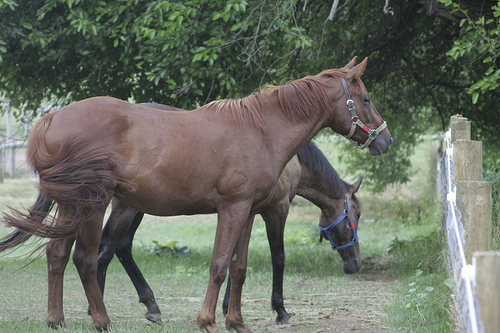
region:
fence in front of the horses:
[438, 101, 499, 331]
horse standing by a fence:
[21, 46, 391, 331]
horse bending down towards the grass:
[82, 135, 371, 322]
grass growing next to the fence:
[395, 198, 451, 325]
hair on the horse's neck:
[207, 63, 342, 141]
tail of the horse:
[22, 117, 122, 239]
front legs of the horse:
[193, 188, 262, 330]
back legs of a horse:
[43, 173, 111, 327]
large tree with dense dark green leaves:
[6, 0, 497, 172]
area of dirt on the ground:
[14, 270, 416, 331]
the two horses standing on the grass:
[1, 55, 392, 332]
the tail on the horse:
[0, 110, 138, 274]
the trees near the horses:
[0, 0, 496, 199]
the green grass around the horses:
[0, 131, 454, 331]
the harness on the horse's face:
[337, 70, 388, 150]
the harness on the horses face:
[317, 192, 357, 252]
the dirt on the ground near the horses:
[264, 258, 394, 331]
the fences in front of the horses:
[429, 111, 498, 331]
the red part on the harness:
[360, 123, 370, 132]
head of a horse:
[310, 39, 397, 159]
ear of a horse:
[332, 49, 379, 81]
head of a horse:
[316, 188, 379, 279]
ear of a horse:
[345, 173, 372, 196]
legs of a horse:
[29, 190, 296, 324]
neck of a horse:
[243, 67, 330, 175]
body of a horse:
[33, 96, 244, 224]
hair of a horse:
[237, 84, 322, 139]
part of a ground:
[325, 298, 334, 315]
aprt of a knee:
[199, 219, 246, 290]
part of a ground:
[356, 271, 366, 293]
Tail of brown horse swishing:
[25, 116, 112, 237]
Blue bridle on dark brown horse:
[315, 192, 357, 247]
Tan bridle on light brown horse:
[336, 77, 385, 149]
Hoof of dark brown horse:
[145, 310, 165, 324]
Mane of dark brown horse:
[298, 145, 348, 197]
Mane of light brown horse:
[220, 71, 337, 116]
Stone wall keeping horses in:
[433, 116, 498, 329]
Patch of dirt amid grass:
[294, 278, 389, 330]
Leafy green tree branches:
[0, 2, 267, 79]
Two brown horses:
[12, 53, 391, 331]